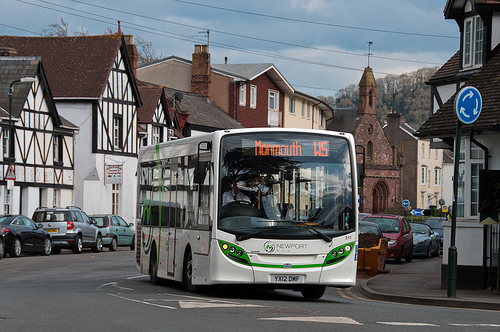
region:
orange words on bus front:
[245, 135, 348, 156]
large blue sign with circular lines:
[440, 78, 491, 131]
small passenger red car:
[364, 203, 423, 258]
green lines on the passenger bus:
[205, 238, 365, 271]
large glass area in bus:
[207, 127, 374, 264]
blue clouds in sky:
[261, 8, 375, 44]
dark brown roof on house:
[43, 30, 146, 112]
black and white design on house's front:
[83, 71, 165, 160]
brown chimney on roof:
[182, 22, 232, 104]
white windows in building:
[443, 7, 498, 62]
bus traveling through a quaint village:
[66, 82, 412, 305]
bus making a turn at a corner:
[96, 100, 473, 321]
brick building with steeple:
[335, 40, 407, 220]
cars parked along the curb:
[5, 195, 135, 251]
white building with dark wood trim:
[10, 50, 130, 215]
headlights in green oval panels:
[210, 232, 365, 272]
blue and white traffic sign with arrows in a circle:
[445, 70, 482, 300]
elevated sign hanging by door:
[87, 145, 124, 190]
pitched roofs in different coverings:
[2, 25, 142, 120]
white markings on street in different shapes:
[90, 268, 486, 328]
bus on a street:
[122, 112, 374, 312]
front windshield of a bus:
[212, 125, 359, 248]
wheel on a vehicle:
[174, 238, 204, 297]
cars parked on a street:
[0, 202, 137, 260]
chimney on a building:
[181, 37, 223, 106]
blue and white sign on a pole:
[439, 75, 487, 176]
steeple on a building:
[344, 32, 388, 137]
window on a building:
[105, 107, 132, 159]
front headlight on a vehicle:
[214, 236, 253, 268]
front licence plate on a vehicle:
[263, 269, 317, 294]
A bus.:
[195, 120, 371, 298]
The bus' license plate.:
[260, 265, 306, 290]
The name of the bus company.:
[252, 230, 318, 257]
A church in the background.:
[330, 30, 400, 215]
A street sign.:
[435, 70, 482, 295]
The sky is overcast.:
[226, 11, 371, 71]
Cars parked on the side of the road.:
[0, 200, 135, 260]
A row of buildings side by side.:
[2, 25, 452, 220]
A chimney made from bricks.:
[185, 35, 212, 97]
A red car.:
[357, 205, 415, 265]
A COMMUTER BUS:
[124, 118, 370, 296]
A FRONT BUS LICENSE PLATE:
[261, 265, 327, 293]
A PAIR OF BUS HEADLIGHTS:
[213, 240, 365, 268]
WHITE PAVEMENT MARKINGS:
[113, 283, 400, 330]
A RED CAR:
[359, 203, 417, 266]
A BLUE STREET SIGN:
[443, 75, 488, 132]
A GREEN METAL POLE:
[444, 138, 464, 302]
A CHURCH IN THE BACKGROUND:
[341, 29, 412, 221]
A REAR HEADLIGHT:
[55, 217, 90, 232]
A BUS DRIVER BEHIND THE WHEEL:
[221, 167, 261, 215]